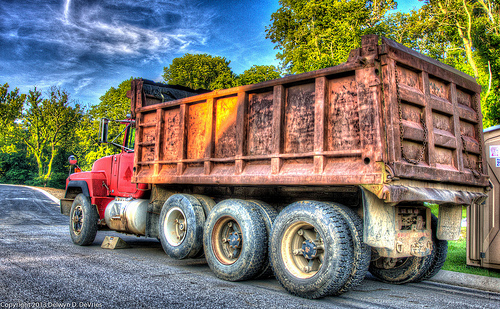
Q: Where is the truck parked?
A: By the curb.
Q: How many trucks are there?
A: One.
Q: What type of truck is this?
A: Dump truck.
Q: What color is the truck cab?
A: Red.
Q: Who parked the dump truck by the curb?
A: The driver.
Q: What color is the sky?
A: Blue.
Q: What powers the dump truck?
A: Fuel.